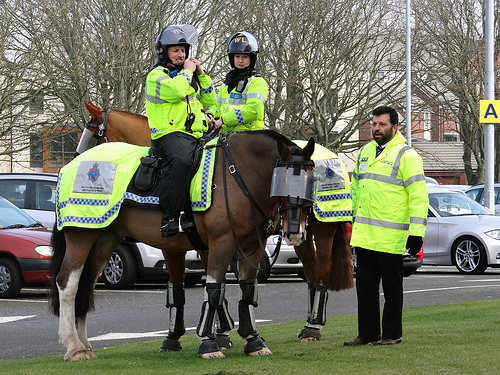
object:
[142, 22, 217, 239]
cop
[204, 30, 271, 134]
cop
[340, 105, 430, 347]
cop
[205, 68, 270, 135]
jacket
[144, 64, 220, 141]
jacket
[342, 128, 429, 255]
jacket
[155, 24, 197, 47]
helmet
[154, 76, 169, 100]
stripe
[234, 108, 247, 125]
stripe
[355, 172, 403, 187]
stripe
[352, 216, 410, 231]
stripe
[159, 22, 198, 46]
visor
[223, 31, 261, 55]
helmet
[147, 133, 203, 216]
pants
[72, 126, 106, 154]
visor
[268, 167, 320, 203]
visor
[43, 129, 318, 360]
horse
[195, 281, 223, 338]
padding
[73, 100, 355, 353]
horse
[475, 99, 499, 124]
sign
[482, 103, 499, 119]
letter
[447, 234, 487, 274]
tire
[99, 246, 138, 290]
tire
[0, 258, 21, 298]
tire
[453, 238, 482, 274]
rim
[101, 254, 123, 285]
rim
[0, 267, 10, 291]
rim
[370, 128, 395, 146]
beard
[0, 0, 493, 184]
trees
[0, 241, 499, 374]
parking lot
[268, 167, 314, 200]
face guard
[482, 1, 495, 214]
pole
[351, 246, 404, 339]
pants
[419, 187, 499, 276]
car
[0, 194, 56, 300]
car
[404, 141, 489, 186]
building